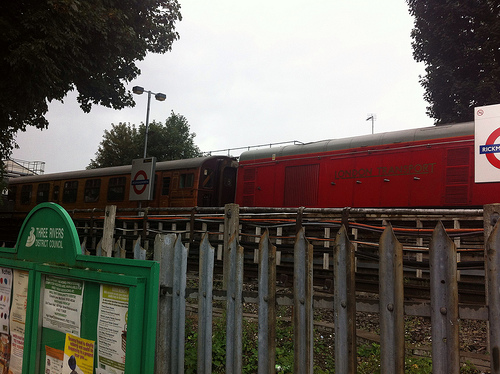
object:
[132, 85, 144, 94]
light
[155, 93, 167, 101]
light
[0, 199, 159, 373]
board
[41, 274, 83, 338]
notices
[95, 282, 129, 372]
notices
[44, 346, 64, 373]
notices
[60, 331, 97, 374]
flyer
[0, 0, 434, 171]
sky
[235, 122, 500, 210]
car train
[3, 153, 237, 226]
car train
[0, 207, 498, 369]
picket fence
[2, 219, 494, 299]
tracks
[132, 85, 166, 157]
street lamp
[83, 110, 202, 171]
tree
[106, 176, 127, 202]
window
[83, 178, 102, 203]
window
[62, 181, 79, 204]
window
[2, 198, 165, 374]
frame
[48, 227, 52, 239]
lettering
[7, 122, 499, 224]
train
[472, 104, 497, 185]
sign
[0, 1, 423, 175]
cloud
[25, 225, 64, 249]
sign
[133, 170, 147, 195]
circle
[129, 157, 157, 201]
sign